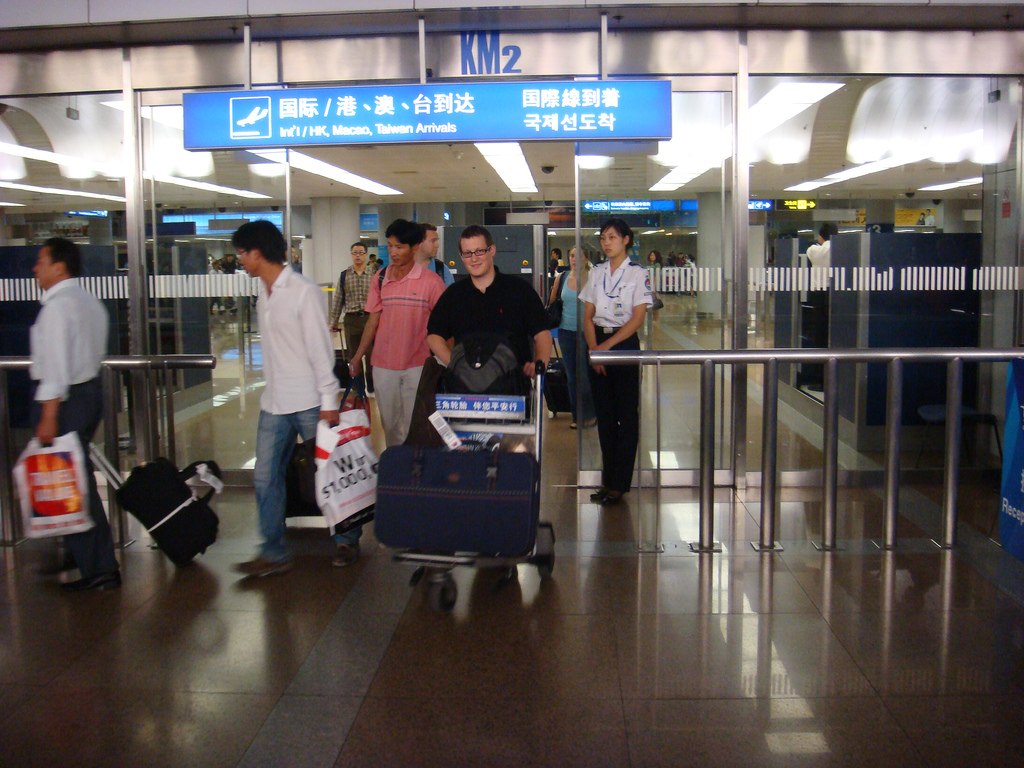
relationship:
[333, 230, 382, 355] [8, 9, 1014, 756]
person in airport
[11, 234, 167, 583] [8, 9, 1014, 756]
person in airport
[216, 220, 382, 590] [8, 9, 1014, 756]
person in airport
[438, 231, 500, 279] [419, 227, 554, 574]
head of person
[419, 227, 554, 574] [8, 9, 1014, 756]
person in airport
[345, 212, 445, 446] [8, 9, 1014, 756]
person in airport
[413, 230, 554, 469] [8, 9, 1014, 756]
person in airport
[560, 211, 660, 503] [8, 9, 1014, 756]
person in airport